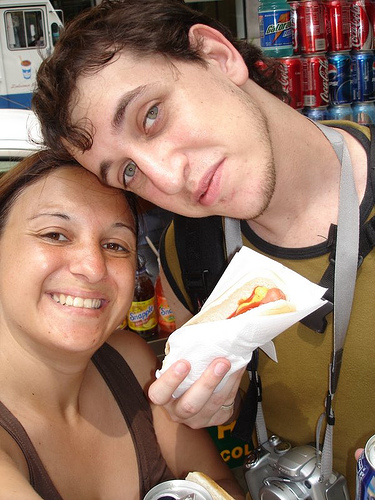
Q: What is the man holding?
A: Hot dog.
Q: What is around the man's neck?
A: Camera.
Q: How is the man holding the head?
A: Top of the woman's head.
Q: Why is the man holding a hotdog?
A: To eat for lunch.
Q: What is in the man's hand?
A: Hotdog.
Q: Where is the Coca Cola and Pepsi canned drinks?
A: Refrigerator.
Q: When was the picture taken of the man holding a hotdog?
A: Noon on Saturday.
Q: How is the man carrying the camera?
A: Strapped around the neck.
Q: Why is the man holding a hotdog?
A: To eat for lunch.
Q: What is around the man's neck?
A: Gray camera.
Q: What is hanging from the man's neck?
A: A camera.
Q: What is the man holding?
A: Hot dog.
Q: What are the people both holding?
A: Soda cans.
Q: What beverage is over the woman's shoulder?
A: Snapple.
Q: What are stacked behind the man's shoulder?
A: Soda.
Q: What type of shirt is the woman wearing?
A: Tank top.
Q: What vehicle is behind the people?
A: A truck.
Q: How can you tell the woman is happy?
A: Smiling.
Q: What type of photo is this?
A: A selfie.